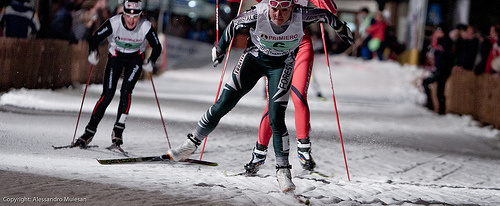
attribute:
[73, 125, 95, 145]
boot — black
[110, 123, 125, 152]
boot — black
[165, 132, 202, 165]
boot — black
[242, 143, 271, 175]
boot — black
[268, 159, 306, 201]
boot — black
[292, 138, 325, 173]
boot — black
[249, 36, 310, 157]
pants — red and black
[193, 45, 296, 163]
pants — green and white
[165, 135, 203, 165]
ski boot — white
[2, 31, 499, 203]
snow — smooth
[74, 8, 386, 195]
men — fast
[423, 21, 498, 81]
people — spectators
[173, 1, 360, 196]
person — skiing 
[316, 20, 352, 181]
pole — red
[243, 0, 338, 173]
skier — athletic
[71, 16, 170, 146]
outfit — black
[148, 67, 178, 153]
ski pole — red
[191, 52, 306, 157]
pants — black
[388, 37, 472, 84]
fence — wooden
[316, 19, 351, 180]
ski pole — red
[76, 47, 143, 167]
pants — black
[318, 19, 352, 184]
ski pole — pink and white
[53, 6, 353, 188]
people — skiing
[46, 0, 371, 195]
men — skiing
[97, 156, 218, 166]
ski — race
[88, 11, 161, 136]
uniform — black and white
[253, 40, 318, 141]
pants — pink